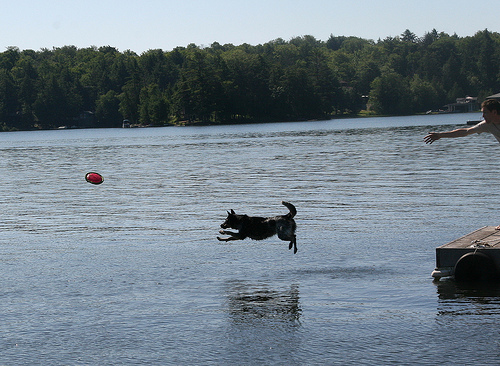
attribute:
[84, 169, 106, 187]
disc — red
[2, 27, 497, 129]
trees — green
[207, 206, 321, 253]
dog — black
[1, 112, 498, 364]
water — blue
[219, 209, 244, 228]
dog ears — black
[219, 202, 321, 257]
dog — black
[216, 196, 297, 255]
dog — black